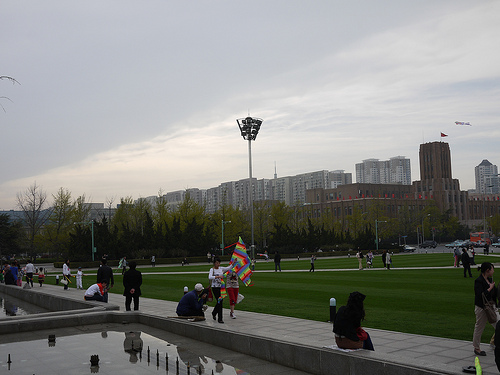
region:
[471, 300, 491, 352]
woman wearing brown pants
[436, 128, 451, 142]
flag on a building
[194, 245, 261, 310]
woman carrying a kite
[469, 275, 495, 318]
woman wearing a black jacket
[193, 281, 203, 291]
man with a white hat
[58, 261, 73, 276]
woman wearing a white shirt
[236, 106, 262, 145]
light on a pole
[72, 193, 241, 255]
trees near the park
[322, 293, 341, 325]
pole in the grass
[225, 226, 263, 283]
rainbow flag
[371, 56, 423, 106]
white clouds in blue sky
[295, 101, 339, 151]
white clouds in blue sky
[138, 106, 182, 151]
white clouds in blue sky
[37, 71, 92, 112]
white clouds in blue sky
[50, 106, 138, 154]
white clouds in blue sky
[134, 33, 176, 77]
white clouds in blue sky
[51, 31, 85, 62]
white clouds in blue sky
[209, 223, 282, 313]
a person holding a kite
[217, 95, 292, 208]
lights on a pole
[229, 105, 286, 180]
lights on a metal pole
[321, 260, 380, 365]
a person sitting down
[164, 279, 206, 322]
a person sitting down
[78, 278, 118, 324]
a person sitting down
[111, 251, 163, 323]
a person walking on sidewalk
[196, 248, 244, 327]
a person walking on sidewalk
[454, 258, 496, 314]
a person walking on sidewalk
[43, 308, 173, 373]
a body of water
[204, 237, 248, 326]
A woman walking holding a colorful kite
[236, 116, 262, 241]
A tall light pole with multiple lights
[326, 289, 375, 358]
A woman sitting on the edge of a fountain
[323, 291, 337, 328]
A small black and white pole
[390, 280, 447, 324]
An area of trimmed green grass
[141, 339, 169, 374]
Water showing a reflection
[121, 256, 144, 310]
A person standing with his arms behind his back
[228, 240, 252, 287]
A rainbow-colored kite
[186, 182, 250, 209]
Distant gray apartment buildings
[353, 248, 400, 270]
People walking on a path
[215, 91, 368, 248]
a light on a pole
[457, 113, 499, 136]
a kite flying in the air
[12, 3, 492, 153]
a sky that is cloudy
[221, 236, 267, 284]
a rainbow colored kite being carried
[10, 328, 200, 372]
the water reflecting in the pond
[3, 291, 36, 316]
more water in the pond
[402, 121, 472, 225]
red brick building in the distance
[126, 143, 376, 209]
city line off in the distance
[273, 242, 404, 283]
people walking on a path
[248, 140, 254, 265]
tall metal pole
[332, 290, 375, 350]
woman sitting on ledge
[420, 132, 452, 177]
red flag on top of a tall building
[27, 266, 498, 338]
green grass beside sidewalk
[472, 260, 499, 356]
woman walking on sidewalk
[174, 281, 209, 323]
man sitting on the cement ledge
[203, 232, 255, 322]
person carrying a colorful kite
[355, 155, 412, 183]
tall gray building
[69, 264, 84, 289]
child walking on the sidewalk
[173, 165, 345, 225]
a row of tall white buildings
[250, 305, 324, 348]
a concrete walk way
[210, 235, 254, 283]
a woman holding a kite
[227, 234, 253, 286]
a multicolored kite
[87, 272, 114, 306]
a person sitting down